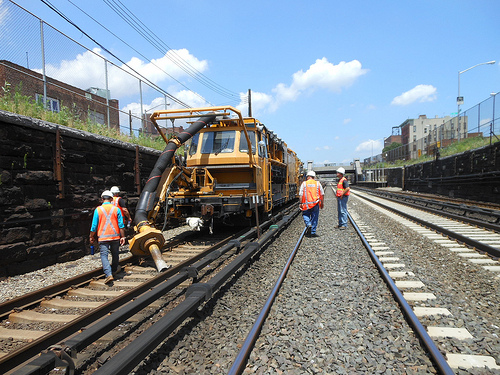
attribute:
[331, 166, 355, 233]
workers — working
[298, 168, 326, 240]
workers — working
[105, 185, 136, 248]
workers — working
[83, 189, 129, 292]
workers — working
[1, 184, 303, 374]
tracks — grey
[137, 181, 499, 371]
gravel — grey, rocks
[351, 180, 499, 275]
tracks — grey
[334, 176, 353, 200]
vest — orange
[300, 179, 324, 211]
vest — orange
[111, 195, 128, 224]
vest — orange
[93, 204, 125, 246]
vest — orange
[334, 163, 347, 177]
hats — white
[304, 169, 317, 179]
hats — white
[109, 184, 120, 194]
hats — white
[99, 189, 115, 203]
hats — white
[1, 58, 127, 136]
building — brick, brown, white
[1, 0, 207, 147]
fence — wire, chain link, metal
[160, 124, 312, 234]
train — yellow, orange, black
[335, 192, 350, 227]
jeans — blue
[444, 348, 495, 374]
concrete — blocks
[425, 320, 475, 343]
concrete — blocks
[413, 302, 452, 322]
concrete — blocks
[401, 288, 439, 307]
concrete — blocks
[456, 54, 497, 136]
pole — light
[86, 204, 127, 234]
shirt — blue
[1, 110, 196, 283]
wall — stone, bricks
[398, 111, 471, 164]
building — concrete, grey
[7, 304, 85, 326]
ties — brown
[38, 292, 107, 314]
ties — brown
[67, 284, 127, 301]
ties — brown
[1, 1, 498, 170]
sky — blue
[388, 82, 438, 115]
clouds — white, puffy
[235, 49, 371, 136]
clouds — white, puffy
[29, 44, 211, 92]
clouds — white, puffy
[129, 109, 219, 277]
hose — large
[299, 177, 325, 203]
shirt — white